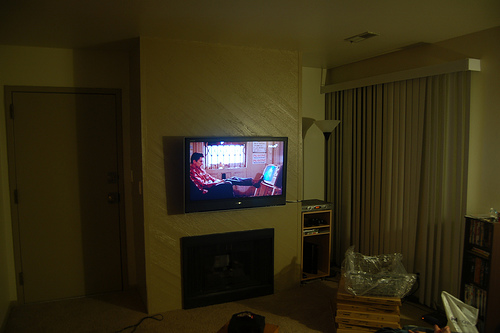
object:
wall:
[136, 43, 373, 303]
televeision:
[166, 134, 288, 211]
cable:
[122, 311, 159, 333]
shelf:
[301, 199, 334, 282]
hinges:
[13, 189, 19, 206]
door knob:
[106, 194, 116, 203]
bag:
[439, 290, 481, 333]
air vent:
[342, 30, 379, 43]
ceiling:
[0, 0, 499, 68]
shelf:
[457, 212, 499, 332]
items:
[461, 201, 500, 333]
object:
[228, 310, 266, 333]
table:
[216, 319, 275, 331]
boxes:
[333, 247, 414, 333]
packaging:
[335, 245, 418, 301]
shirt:
[190, 165, 219, 193]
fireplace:
[178, 226, 277, 307]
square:
[177, 227, 275, 306]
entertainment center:
[300, 209, 335, 283]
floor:
[0, 302, 224, 333]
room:
[0, 0, 500, 333]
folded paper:
[447, 206, 499, 332]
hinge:
[10, 103, 15, 119]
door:
[12, 85, 126, 305]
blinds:
[327, 58, 484, 295]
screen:
[185, 140, 285, 204]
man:
[189, 152, 265, 195]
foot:
[253, 173, 264, 188]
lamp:
[312, 118, 339, 201]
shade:
[312, 116, 342, 135]